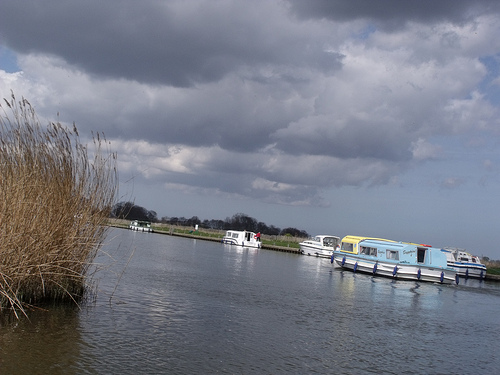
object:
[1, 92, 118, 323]
rushes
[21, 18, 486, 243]
sky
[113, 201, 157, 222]
trees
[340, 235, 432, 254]
roof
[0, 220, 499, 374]
waterway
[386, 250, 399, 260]
window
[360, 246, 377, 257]
window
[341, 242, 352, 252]
window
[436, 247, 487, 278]
boat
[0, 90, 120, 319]
cat tails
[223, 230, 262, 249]
boat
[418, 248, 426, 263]
door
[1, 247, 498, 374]
water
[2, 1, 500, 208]
cloud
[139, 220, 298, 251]
land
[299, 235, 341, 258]
boat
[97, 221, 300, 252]
shore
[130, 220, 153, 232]
boats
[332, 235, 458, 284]
boat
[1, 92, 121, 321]
reeds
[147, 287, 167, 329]
light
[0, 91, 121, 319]
bushes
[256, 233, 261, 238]
jacket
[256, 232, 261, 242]
person